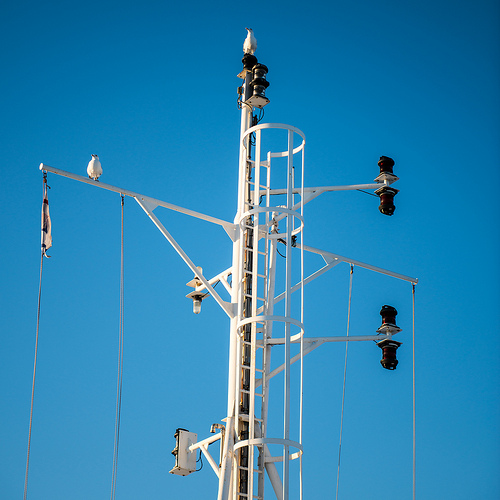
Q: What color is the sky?
A: Blue.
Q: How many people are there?
A: None.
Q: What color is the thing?
A: White.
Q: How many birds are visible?
A: Two.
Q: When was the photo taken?
A: Daytime.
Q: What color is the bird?
A: Yellow and white.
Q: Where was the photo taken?
A: Behind a power pole.